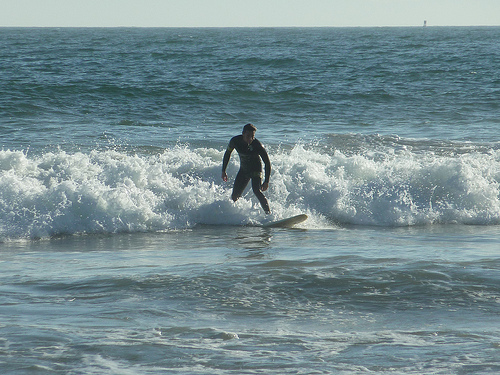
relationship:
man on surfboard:
[218, 122, 278, 219] [257, 212, 306, 231]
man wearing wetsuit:
[218, 122, 278, 219] [224, 135, 270, 213]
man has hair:
[218, 122, 278, 219] [239, 123, 256, 135]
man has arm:
[218, 122, 278, 219] [259, 140, 272, 192]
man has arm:
[218, 122, 278, 219] [221, 140, 235, 186]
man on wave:
[218, 122, 278, 219] [3, 141, 499, 237]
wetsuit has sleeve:
[224, 135, 270, 213] [260, 140, 275, 175]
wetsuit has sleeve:
[224, 135, 270, 213] [221, 137, 234, 167]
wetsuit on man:
[224, 135, 270, 213] [218, 122, 278, 219]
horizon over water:
[1, 22, 499, 30] [0, 21, 499, 374]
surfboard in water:
[257, 212, 306, 231] [0, 21, 499, 374]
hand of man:
[258, 180, 274, 192] [218, 122, 278, 219]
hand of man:
[221, 171, 229, 183] [218, 122, 278, 219]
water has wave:
[0, 21, 499, 374] [3, 141, 499, 237]